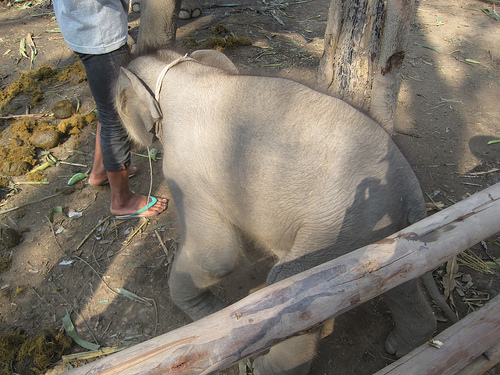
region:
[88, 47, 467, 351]
small grey baby elephant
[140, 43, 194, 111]
baby elephant wearing a cable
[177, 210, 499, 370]
wood fence behind elephant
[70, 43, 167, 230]
person wearing denim jeans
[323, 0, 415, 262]
tree trunk next to baby elephant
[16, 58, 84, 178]
elephant poop on the ground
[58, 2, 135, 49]
light blue t shirt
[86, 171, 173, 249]
light blue flip flops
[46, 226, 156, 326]
leaves and twigs on the ground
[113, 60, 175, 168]
elephant has floppy folded ears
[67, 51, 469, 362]
the elephant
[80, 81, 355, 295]
the elephant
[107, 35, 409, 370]
Baby elephant with head down approaches human in pen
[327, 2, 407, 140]
Medium trunk of tree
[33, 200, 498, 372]
Safety railing of enclosure, made from large, sanded logs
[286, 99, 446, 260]
Shadow of person taking a photograph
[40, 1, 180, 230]
Bottom half of person standing in elephant enclosure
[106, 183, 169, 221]
Teal flip flop worn by person in enclosure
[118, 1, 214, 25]
Elephant toes behind tree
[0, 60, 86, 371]
Large piles of elephant feces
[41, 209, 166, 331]
Scattered twigs and leaves on ground of enclosure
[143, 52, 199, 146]
Light-colored string around baby elephant's neck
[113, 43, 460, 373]
one grey baby elephant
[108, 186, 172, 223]
one blue flip flop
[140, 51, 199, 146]
elephant leash made of rope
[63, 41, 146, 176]
paid of grey jeans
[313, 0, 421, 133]
tan tree trunk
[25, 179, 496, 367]
wooden two spoke fence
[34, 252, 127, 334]
patch of dirt ground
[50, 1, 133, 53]
bottom of white shirt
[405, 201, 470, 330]
baby elephant tail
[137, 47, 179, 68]
black hair on baby elephant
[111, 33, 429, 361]
a baby elephant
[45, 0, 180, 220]
a child next to the elephant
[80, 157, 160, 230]
teal flip flops on the child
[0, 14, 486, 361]
a dirt covered landscape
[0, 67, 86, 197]
a pile of elephant excrement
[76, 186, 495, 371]
a wooden fence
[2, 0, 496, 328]
leaves scattered on the ground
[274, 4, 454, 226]
the trunk of a tree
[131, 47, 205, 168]
a rope around the elephant's neck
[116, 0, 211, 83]
the trunk of a tree